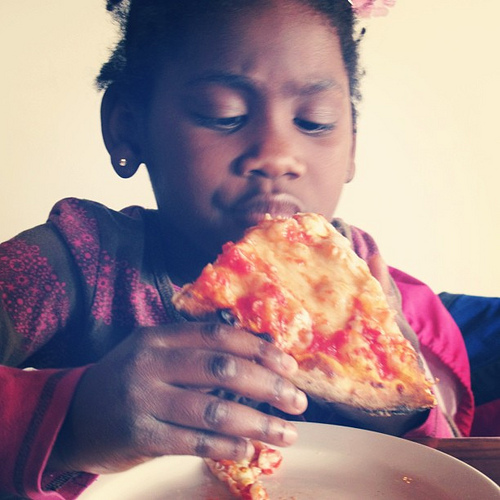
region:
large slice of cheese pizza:
[164, 198, 461, 433]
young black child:
[1, 4, 480, 464]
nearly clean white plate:
[35, 393, 492, 498]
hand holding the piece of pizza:
[53, 327, 330, 478]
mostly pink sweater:
[0, 194, 474, 491]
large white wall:
[0, 4, 499, 150]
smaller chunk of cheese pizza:
[174, 417, 299, 498]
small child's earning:
[110, 154, 130, 169]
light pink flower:
[341, 1, 405, 34]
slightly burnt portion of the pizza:
[208, 305, 242, 332]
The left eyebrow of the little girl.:
[183, 59, 267, 96]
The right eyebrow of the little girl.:
[284, 71, 346, 101]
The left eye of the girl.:
[187, 100, 251, 132]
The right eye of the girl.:
[286, 109, 338, 140]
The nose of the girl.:
[235, 145, 310, 184]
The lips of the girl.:
[233, 194, 306, 231]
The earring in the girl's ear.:
[107, 151, 139, 176]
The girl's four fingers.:
[128, 322, 298, 465]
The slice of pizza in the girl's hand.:
[182, 213, 433, 420]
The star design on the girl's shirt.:
[14, 180, 179, 340]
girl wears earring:
[105, 126, 130, 210]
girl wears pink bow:
[357, 1, 397, 46]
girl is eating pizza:
[145, 217, 445, 430]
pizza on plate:
[188, 430, 273, 498]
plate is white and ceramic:
[75, 392, 412, 484]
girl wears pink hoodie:
[28, 192, 181, 339]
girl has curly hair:
[72, 1, 229, 126]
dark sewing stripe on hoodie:
[17, 368, 84, 493]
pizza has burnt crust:
[239, 336, 443, 425]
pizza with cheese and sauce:
[202, 215, 438, 419]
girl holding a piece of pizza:
[84, 58, 473, 444]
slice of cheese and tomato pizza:
[212, 217, 425, 399]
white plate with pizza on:
[102, 430, 479, 493]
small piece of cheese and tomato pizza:
[206, 445, 278, 495]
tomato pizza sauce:
[304, 339, 347, 359]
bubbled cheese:
[290, 248, 332, 305]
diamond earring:
[115, 155, 127, 165]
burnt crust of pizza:
[322, 392, 439, 417]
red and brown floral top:
[10, 209, 178, 333]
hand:
[84, 302, 301, 462]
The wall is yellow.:
[416, 56, 488, 156]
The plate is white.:
[65, 412, 499, 496]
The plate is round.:
[55, 417, 499, 498]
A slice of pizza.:
[175, 207, 437, 424]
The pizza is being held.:
[105, 208, 445, 480]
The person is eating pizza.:
[80, 0, 452, 412]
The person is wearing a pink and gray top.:
[0, 188, 472, 498]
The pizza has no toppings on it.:
[165, 212, 452, 418]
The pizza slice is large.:
[176, 200, 443, 419]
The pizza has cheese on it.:
[158, 205, 443, 420]